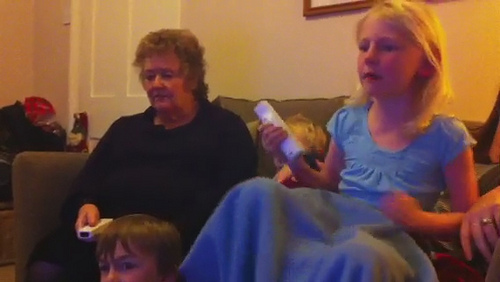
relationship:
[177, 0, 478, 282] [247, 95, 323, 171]
girl holding wii controller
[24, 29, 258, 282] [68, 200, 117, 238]
grandma holding wii controller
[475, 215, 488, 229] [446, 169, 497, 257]
wedding band on hand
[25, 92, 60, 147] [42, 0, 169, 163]
bag behind door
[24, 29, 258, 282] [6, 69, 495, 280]
grandma sitting on couch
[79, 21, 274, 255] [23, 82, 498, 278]
grandma sitting on couch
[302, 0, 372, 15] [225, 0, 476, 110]
picture on wall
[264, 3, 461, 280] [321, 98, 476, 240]
girl wearing shirt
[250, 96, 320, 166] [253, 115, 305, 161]
controller in hand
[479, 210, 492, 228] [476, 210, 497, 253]
ring on finger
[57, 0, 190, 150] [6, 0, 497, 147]
door on wall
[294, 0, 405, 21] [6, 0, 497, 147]
picture on wall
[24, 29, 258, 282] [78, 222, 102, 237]
grandma holding controller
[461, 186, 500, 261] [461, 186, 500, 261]
hand has a hand